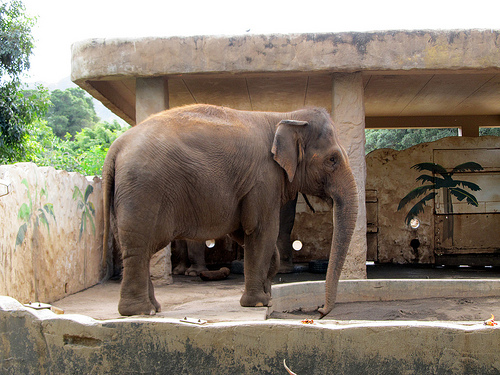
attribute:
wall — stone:
[2, 295, 498, 374]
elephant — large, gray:
[100, 103, 357, 316]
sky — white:
[2, 0, 497, 126]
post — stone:
[321, 76, 370, 280]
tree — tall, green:
[0, 0, 39, 161]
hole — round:
[203, 236, 216, 248]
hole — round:
[289, 235, 306, 253]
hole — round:
[405, 213, 421, 230]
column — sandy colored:
[327, 70, 370, 279]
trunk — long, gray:
[318, 159, 360, 317]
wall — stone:
[2, 156, 108, 306]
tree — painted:
[398, 159, 484, 257]